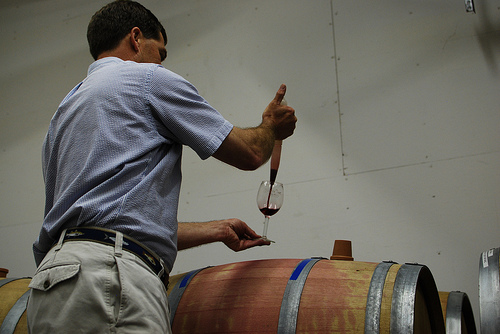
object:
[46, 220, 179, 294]
belt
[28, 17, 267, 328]
man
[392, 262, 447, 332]
metal rim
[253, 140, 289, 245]
red wine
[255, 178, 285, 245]
glass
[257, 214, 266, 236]
stem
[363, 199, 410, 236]
ground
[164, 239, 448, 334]
barrel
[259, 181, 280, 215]
wine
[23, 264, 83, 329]
back pocket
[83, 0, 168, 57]
hair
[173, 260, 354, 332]
red stain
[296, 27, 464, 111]
ground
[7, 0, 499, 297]
walls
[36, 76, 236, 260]
shirt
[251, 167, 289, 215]
sample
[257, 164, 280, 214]
sample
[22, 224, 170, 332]
pants